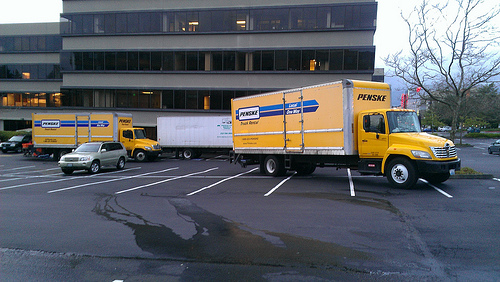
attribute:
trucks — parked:
[68, 93, 392, 186]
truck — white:
[146, 113, 240, 164]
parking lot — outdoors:
[5, 133, 498, 279]